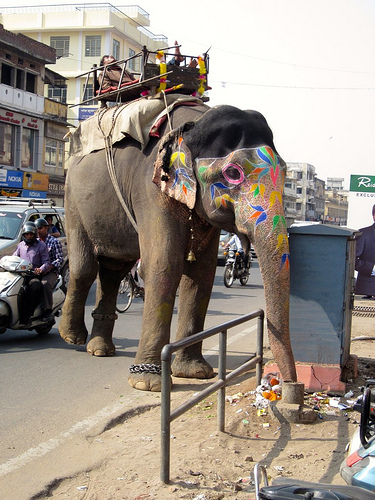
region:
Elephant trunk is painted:
[216, 154, 306, 358]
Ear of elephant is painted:
[153, 130, 199, 213]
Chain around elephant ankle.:
[119, 345, 199, 382]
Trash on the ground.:
[252, 375, 342, 421]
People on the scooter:
[16, 216, 74, 322]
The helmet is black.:
[22, 220, 39, 236]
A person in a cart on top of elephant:
[80, 55, 212, 94]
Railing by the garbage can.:
[160, 334, 279, 430]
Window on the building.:
[45, 25, 110, 61]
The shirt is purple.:
[14, 244, 46, 264]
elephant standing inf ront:
[51, 96, 281, 392]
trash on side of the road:
[256, 381, 320, 411]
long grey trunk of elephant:
[255, 203, 301, 382]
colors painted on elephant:
[246, 174, 290, 251]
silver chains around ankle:
[135, 360, 173, 380]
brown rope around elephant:
[97, 151, 132, 237]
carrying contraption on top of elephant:
[68, 49, 209, 107]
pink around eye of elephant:
[219, 161, 244, 190]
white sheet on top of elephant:
[60, 108, 156, 159]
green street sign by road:
[352, 172, 372, 193]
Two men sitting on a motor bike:
[1, 212, 64, 336]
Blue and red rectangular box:
[255, 219, 363, 395]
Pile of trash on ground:
[230, 360, 373, 416]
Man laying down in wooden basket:
[70, 44, 212, 106]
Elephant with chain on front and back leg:
[59, 91, 304, 390]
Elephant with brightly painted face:
[55, 89, 297, 393]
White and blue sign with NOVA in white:
[2, 167, 23, 190]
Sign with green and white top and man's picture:
[345, 174, 373, 296]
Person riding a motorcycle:
[222, 228, 252, 289]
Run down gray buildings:
[280, 158, 351, 229]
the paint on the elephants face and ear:
[170, 133, 294, 279]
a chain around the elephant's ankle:
[127, 359, 167, 382]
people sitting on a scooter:
[6, 216, 62, 318]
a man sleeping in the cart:
[89, 53, 204, 83]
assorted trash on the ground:
[249, 373, 347, 424]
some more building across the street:
[279, 157, 348, 225]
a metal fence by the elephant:
[151, 312, 262, 458]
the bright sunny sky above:
[180, 13, 373, 141]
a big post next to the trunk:
[283, 217, 345, 390]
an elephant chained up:
[37, 12, 372, 353]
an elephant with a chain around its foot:
[30, 92, 348, 491]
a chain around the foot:
[126, 314, 212, 415]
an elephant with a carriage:
[42, 42, 367, 433]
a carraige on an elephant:
[43, 32, 355, 318]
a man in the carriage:
[51, 12, 240, 216]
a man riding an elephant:
[71, 49, 279, 199]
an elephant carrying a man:
[48, 33, 306, 270]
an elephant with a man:
[59, 27, 289, 249]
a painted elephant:
[177, 113, 371, 377]